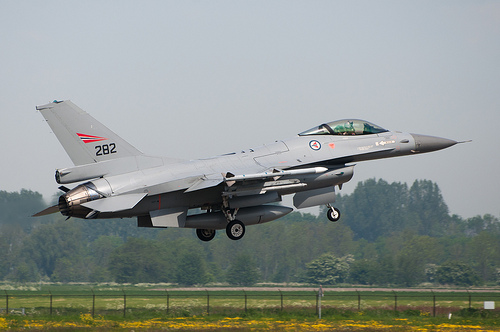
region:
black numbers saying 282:
[93, 141, 116, 156]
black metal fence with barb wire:
[0, 287, 499, 315]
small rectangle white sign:
[483, 299, 497, 310]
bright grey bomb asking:
[174, 201, 295, 231]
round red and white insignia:
[309, 138, 321, 151]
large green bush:
[306, 249, 349, 286]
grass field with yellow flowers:
[3, 313, 498, 330]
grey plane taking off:
[42, 79, 420, 268]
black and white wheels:
[195, 191, 352, 235]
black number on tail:
[82, 134, 124, 157]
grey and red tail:
[40, 102, 110, 156]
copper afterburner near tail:
[63, 166, 88, 220]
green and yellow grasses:
[28, 306, 465, 329]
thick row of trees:
[3, 207, 465, 292]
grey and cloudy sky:
[110, 41, 233, 88]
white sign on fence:
[470, 299, 497, 320]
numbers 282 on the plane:
[87, 130, 130, 160]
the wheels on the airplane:
[230, 225, 242, 239]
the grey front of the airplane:
[421, 122, 454, 155]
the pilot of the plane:
[318, 110, 356, 132]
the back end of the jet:
[48, 188, 90, 217]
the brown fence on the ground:
[145, 293, 175, 313]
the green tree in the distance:
[301, 255, 338, 285]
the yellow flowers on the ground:
[435, 318, 450, 328]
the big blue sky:
[415, 69, 464, 101]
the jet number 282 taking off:
[39, 121, 385, 222]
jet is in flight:
[34, 99, 484, 254]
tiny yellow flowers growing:
[133, 318, 478, 330]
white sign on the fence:
[468, 293, 499, 315]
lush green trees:
[360, 178, 490, 290]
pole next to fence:
[308, 283, 334, 323]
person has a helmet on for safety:
[335, 119, 379, 132]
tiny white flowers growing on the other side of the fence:
[108, 288, 265, 310]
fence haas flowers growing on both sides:
[6, 286, 303, 324]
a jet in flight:
[31, 101, 475, 236]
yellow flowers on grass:
[0, 309, 493, 329]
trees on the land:
[367, 188, 432, 279]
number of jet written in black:
[89, 140, 124, 160]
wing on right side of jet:
[226, 160, 330, 187]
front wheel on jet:
[315, 201, 345, 217]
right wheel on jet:
[225, 218, 247, 239]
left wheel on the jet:
[196, 225, 214, 240]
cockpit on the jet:
[327, 121, 385, 135]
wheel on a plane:
[315, 197, 350, 223]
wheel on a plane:
[210, 213, 253, 244]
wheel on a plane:
[182, 223, 214, 243]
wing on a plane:
[31, 100, 141, 167]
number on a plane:
[86, 130, 117, 163]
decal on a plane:
[303, 140, 323, 155]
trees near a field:
[420, 207, 486, 267]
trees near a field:
[361, 175, 411, 241]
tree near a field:
[223, 247, 283, 287]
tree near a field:
[170, 240, 210, 285]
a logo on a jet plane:
[78, 127, 107, 145]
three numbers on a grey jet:
[93, 140, 118, 155]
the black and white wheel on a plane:
[329, 205, 343, 222]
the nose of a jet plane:
[413, 131, 470, 151]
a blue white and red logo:
[308, 137, 324, 151]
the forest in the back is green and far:
[366, 190, 451, 276]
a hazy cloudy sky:
[147, 10, 272, 98]